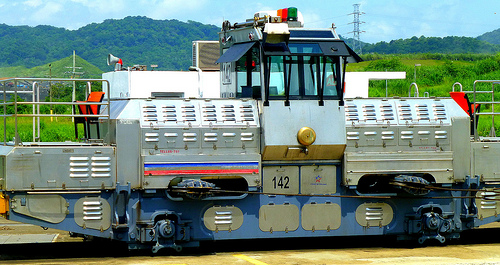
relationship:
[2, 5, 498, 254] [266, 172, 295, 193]
vehicle has a number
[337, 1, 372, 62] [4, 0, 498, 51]
radio tower on background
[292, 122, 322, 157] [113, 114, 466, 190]
bell on side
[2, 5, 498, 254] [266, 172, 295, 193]
train number 142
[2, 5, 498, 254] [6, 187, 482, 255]
train blue on bottom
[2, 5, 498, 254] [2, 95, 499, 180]
train top silver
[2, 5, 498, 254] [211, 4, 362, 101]
train has window cage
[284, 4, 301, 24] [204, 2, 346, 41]
green light on top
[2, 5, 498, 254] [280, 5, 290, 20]
train has red light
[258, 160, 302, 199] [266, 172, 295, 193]
vehicle window label 142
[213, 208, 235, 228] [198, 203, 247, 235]
vents in octagonal placement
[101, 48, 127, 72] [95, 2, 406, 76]
horn on top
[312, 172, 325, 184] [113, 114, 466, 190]
star logo on side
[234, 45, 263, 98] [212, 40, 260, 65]
window has blue teal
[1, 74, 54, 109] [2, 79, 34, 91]
parking lot with few vehicles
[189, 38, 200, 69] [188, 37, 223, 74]
air conditioner atop building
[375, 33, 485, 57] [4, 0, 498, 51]
trees in background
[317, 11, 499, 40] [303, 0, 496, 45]
electric wires in air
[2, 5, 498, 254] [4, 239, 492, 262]
car on train tracks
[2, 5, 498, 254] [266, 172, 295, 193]
vehicle number hundred forty-two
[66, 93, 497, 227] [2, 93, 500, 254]
air vents over structure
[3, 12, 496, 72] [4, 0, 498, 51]
wooded hills in background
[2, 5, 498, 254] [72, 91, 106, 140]
train with chair